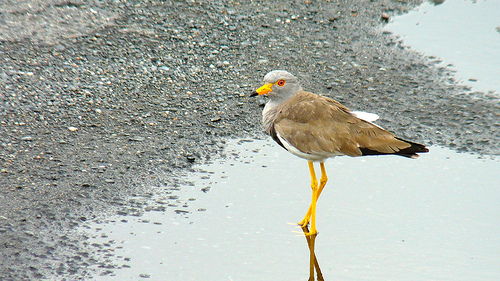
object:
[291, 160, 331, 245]
wading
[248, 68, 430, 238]
bird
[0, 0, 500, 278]
beach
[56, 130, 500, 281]
water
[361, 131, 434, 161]
tail feathers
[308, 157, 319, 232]
legs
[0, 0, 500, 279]
ground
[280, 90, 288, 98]
gray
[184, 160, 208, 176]
stones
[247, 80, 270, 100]
beak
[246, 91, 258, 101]
tip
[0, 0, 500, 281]
shore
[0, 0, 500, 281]
gravel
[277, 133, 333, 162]
belly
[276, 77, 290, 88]
eye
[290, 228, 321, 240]
foot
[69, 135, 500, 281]
puddle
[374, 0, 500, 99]
puddle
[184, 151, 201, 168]
rock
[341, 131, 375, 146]
feathers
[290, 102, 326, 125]
brown feather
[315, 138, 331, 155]
tan feathers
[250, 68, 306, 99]
head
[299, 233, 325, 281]
reflection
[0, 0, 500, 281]
road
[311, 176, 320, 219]
yellow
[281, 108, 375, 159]
wing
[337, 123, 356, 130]
brown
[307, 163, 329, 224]
bent leg